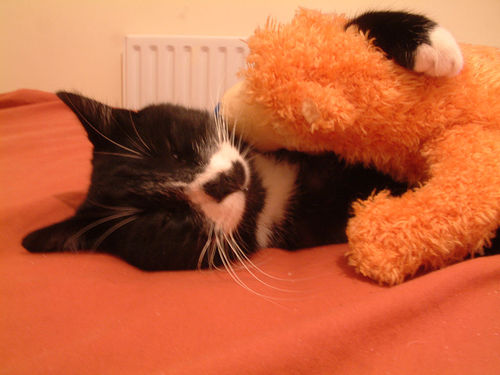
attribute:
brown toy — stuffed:
[225, 5, 498, 276]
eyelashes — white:
[74, 131, 161, 261]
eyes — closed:
[136, 129, 201, 251]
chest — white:
[249, 151, 340, 248]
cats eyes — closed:
[163, 122, 178, 299]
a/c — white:
[123, 32, 255, 120]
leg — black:
[362, 19, 497, 100]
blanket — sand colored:
[0, 85, 499, 374]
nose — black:
[201, 171, 266, 208]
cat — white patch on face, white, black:
[12, 4, 499, 286]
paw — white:
[393, 4, 472, 89]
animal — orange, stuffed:
[209, 20, 499, 263]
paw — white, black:
[358, 9, 465, 80]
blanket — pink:
[179, 276, 335, 360]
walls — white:
[16, 21, 92, 61]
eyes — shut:
[156, 207, 213, 242]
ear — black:
[19, 218, 104, 258]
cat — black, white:
[56, 82, 330, 211]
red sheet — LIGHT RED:
[8, 98, 498, 337]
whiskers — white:
[191, 222, 315, 316]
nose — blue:
[211, 100, 223, 117]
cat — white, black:
[3, 46, 425, 364]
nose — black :
[203, 158, 248, 205]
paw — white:
[395, 16, 463, 88]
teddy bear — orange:
[212, 3, 497, 283]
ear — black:
[52, 79, 126, 154]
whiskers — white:
[195, 218, 311, 314]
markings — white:
[243, 142, 308, 256]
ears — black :
[46, 82, 109, 132]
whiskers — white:
[191, 206, 275, 301]